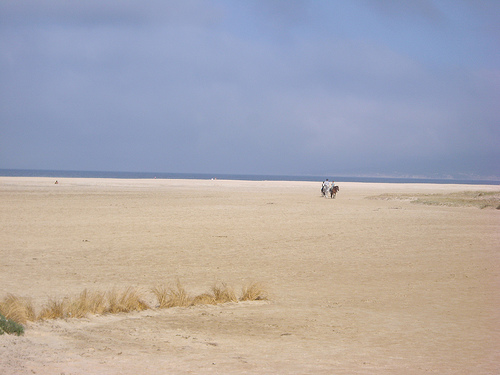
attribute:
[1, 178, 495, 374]
ground — brown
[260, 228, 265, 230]
sand grain — tan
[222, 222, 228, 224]
sand grain — tan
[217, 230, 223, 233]
sand grain — tan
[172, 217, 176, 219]
sand grain — tan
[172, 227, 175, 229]
sand grain — tan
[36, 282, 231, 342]
grass — green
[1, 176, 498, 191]
shoreline — sandy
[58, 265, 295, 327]
grass — yellow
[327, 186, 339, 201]
horse — brown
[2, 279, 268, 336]
grass — brown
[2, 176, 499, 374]
beach — large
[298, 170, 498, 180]
mountains — distant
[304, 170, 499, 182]
land — distant